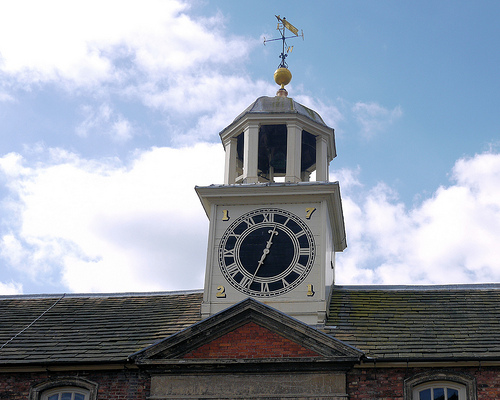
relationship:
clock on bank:
[200, 190, 339, 316] [0, 16, 500, 400]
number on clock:
[240, 210, 267, 237] [200, 190, 339, 316]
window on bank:
[385, 360, 485, 398] [0, 16, 500, 400]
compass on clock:
[258, 10, 311, 100] [197, 183, 338, 313]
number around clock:
[213, 198, 243, 230] [187, 183, 342, 311]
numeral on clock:
[222, 218, 249, 249] [205, 188, 328, 310]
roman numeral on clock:
[297, 244, 311, 255] [214, 204, 320, 302]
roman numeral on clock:
[288, 260, 309, 278] [214, 204, 320, 302]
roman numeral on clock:
[258, 277, 272, 294] [214, 204, 320, 302]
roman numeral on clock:
[238, 270, 255, 293] [214, 204, 320, 302]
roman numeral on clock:
[223, 259, 244, 280] [214, 204, 320, 302]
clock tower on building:
[190, 10, 350, 332] [3, 274, 495, 399]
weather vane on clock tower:
[252, 9, 306, 97] [187, 90, 352, 331]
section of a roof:
[374, 298, 448, 341] [2, 281, 499, 367]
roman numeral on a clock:
[277, 276, 294, 290] [205, 195, 321, 332]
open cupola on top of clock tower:
[190, 80, 343, 175] [140, 100, 370, 348]